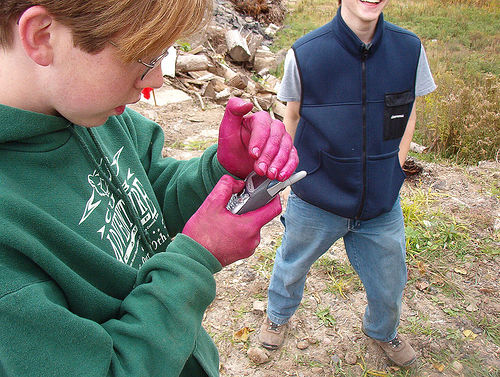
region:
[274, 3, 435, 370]
This is a person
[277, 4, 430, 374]
This is a person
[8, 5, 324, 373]
This is a person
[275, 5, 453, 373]
This is a person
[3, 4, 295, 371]
This is a person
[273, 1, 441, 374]
This is a person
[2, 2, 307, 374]
This is a person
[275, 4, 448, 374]
This is a person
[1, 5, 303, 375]
This is a person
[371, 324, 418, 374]
hiking boots on the person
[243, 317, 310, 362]
hiking boots on the person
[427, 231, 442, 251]
patch of green grass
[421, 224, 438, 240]
patch of green grass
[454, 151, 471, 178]
patch of green grass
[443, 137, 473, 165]
patch of green grass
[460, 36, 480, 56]
patch of green grass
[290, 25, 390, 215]
boy has blue vest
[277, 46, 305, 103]
boy has grey shirt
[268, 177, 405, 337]
boy has blue pants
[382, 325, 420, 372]
boy has brown shoes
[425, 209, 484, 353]
green and brown ground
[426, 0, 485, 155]
weedy grass behind boys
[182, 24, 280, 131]
brown logs behind boy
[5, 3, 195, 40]
child has red hair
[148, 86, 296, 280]
child has pink hands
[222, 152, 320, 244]
child holds grey cell phone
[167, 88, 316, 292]
red stained hands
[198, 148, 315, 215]
silver cell phone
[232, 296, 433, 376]
pair of brown boots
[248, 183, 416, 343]
pair of blue jeans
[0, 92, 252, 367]
green sweatshirt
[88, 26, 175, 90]
glasses on face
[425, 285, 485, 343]
brown leaves on ground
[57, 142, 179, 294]
white letters and design on front of green sweatshirt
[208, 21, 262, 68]
fallen log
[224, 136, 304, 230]
a person holding a phone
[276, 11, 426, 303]
a boy wearing a jacket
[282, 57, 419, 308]
a boy wearing pants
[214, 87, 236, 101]
A chunk of wood on the ground.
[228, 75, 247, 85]
A chunk of wood on the ground.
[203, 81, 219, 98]
A chunk of wood on the ground.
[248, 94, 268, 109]
A chunk of wood on the ground.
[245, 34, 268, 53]
A chunk of wood on the ground.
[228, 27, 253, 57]
A chunk of wood on the ground.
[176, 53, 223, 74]
A chunk of wood on the ground.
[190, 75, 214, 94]
A chunk of wood on the ground.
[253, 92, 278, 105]
A chunk of wood on the ground.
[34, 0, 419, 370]
these are two people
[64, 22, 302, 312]
the boy is looking at the phone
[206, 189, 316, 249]
this is a phone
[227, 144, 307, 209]
the phone is gray and white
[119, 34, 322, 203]
the hands are pink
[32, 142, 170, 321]
the hoodie is green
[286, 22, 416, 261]
the vest is blue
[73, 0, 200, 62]
the hair is dirty blonde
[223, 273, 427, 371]
the shoes are brown